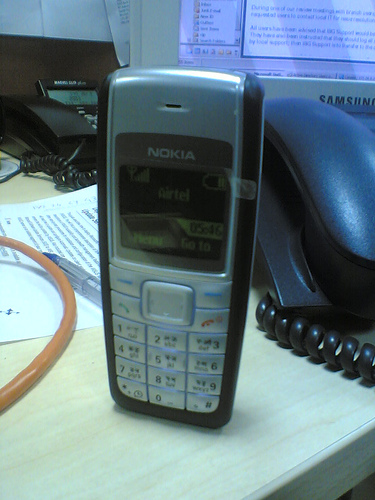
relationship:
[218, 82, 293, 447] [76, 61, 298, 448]
casing on phone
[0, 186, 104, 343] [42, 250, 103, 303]
paper with a pen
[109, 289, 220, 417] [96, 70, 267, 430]
number pad on cell phone